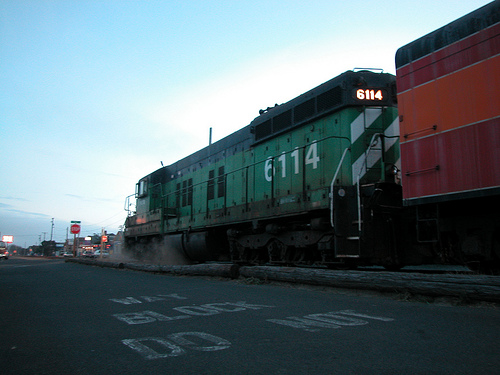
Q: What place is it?
A: It is a road.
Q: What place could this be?
A: It is a road.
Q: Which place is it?
A: It is a road.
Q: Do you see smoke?
A: Yes, there is smoke.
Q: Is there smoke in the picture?
A: Yes, there is smoke.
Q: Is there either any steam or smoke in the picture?
A: Yes, there is smoke.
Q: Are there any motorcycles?
A: No, there are no motorcycles.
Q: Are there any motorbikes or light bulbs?
A: No, there are no motorbikes or light bulbs.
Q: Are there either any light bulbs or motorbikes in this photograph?
A: No, there are no motorbikes or light bulbs.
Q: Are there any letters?
A: Yes, there are letters.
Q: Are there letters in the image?
A: Yes, there are letters.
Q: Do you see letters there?
A: Yes, there are letters.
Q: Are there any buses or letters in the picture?
A: Yes, there are letters.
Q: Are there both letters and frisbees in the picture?
A: No, there are letters but no frisbees.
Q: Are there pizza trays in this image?
A: No, there are no pizza trays.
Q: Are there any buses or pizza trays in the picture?
A: No, there are no pizza trays or buses.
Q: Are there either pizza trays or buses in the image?
A: No, there are no pizza trays or buses.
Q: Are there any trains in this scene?
A: Yes, there is a train.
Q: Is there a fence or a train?
A: Yes, there is a train.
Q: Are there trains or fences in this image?
A: Yes, there is a train.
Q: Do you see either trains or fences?
A: Yes, there is a train.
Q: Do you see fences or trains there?
A: Yes, there is a train.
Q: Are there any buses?
A: No, there are no buses.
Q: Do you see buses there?
A: No, there are no buses.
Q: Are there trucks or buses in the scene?
A: No, there are no buses or trucks.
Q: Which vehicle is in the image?
A: The vehicle is a train.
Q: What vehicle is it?
A: The vehicle is a train.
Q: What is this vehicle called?
A: This is a train.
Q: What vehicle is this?
A: This is a train.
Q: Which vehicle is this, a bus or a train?
A: This is a train.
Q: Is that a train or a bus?
A: That is a train.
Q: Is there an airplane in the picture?
A: No, there are no airplanes.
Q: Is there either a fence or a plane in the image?
A: No, there are no airplanes or fences.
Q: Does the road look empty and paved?
A: Yes, the road is empty and paved.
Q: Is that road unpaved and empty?
A: No, the road is empty but paved.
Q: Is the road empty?
A: Yes, the road is empty.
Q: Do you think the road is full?
A: No, the road is empty.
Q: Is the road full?
A: No, the road is empty.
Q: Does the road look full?
A: No, the road is empty.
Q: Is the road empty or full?
A: The road is empty.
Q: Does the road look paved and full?
A: No, the road is paved but empty.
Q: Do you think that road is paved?
A: Yes, the road is paved.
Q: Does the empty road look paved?
A: Yes, the road is paved.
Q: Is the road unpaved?
A: No, the road is paved.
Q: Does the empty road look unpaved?
A: No, the road is paved.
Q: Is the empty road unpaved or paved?
A: The road is paved.